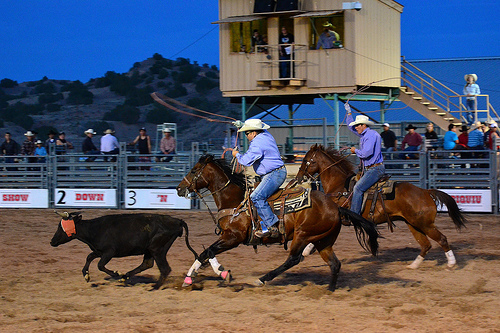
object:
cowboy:
[343, 103, 386, 223]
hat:
[34, 140, 44, 145]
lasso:
[150, 90, 237, 124]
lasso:
[345, 77, 416, 114]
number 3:
[128, 190, 136, 205]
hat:
[349, 115, 375, 127]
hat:
[139, 127, 147, 132]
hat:
[84, 128, 97, 134]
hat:
[24, 131, 35, 137]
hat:
[162, 128, 172, 133]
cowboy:
[231, 118, 288, 237]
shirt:
[346, 114, 391, 167]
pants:
[249, 167, 288, 224]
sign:
[55, 188, 118, 207]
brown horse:
[176, 153, 379, 293]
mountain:
[0, 53, 242, 151]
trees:
[177, 70, 197, 83]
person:
[81, 128, 100, 168]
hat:
[104, 129, 116, 133]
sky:
[0, 0, 500, 83]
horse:
[295, 144, 469, 271]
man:
[398, 124, 424, 160]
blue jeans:
[399, 145, 420, 160]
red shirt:
[401, 132, 422, 150]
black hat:
[405, 123, 417, 130]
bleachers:
[381, 122, 500, 173]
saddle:
[246, 179, 313, 218]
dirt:
[1, 210, 500, 332]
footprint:
[438, 301, 451, 308]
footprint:
[403, 306, 428, 315]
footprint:
[363, 291, 385, 299]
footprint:
[308, 288, 334, 300]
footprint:
[474, 247, 499, 261]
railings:
[398, 87, 462, 134]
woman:
[464, 73, 481, 123]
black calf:
[50, 210, 199, 291]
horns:
[54, 210, 69, 219]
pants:
[101, 150, 117, 161]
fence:
[0, 141, 500, 211]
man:
[100, 129, 122, 162]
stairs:
[399, 56, 500, 134]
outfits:
[232, 118, 287, 237]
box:
[214, 0, 405, 99]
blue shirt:
[236, 129, 285, 176]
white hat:
[465, 73, 478, 81]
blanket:
[273, 187, 312, 215]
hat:
[237, 118, 271, 133]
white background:
[125, 189, 193, 210]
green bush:
[103, 102, 143, 124]